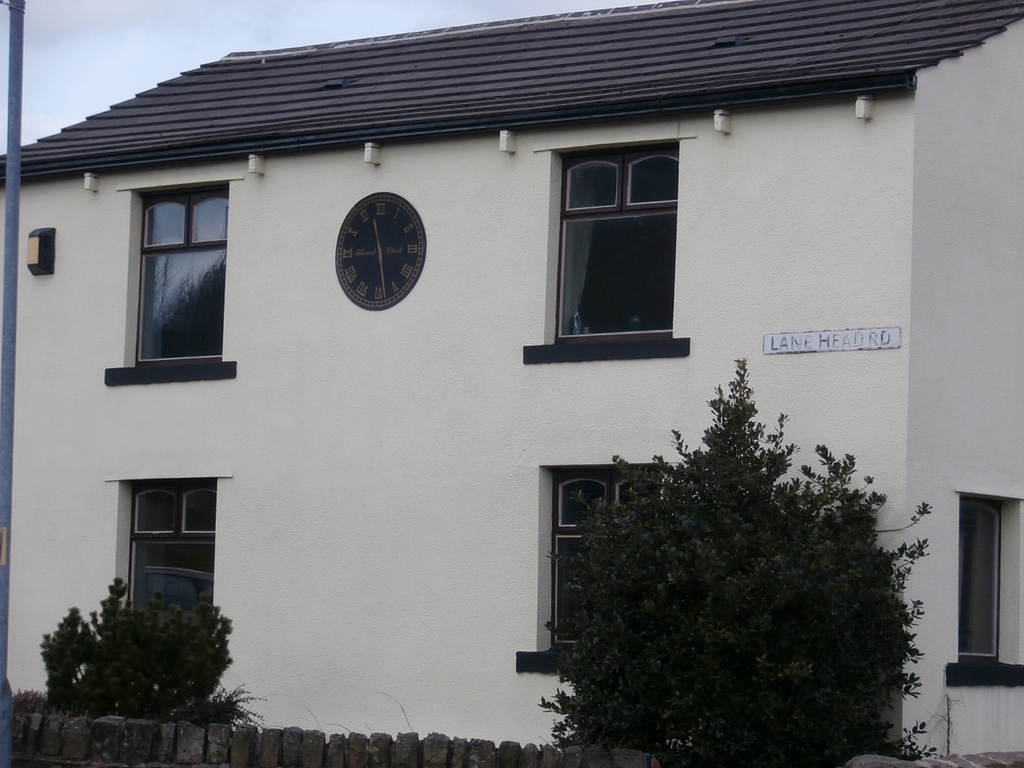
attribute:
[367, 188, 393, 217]
numeral — gold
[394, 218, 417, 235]
numeral — gold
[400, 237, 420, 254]
numeral — gold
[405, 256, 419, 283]
numeral — gold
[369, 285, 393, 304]
numeral — gold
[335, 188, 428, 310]
clock face — black, round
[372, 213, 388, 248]
hand — gold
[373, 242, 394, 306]
hand — gold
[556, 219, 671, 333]
window — square 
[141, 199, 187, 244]
plate glass — small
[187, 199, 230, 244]
plate glass — small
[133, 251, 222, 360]
window — square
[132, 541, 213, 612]
window — square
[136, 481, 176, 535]
plate glass — small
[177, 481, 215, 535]
plate glass — small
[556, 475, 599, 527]
plate glass — small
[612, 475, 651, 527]
plate glass — small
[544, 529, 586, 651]
window — square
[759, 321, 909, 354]
sign — white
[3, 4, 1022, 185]
roof — dark gray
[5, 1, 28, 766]
pole — tall, silver, metal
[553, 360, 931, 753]
bush — tall , green 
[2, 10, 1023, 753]
building — white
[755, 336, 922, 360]
letters — black